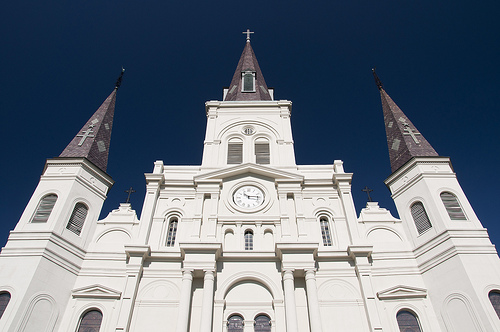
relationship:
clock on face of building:
[222, 175, 285, 215] [10, 19, 493, 328]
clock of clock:
[222, 175, 285, 215] [230, 179, 266, 213]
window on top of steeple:
[241, 70, 259, 95] [219, 32, 279, 106]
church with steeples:
[6, 21, 498, 330] [39, 26, 440, 193]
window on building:
[242, 221, 256, 250] [10, 19, 493, 328]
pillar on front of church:
[177, 272, 197, 331] [6, 21, 498, 330]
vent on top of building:
[235, 117, 256, 137] [10, 19, 493, 328]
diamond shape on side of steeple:
[382, 132, 407, 161] [366, 84, 442, 178]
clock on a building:
[222, 175, 285, 215] [10, 19, 493, 328]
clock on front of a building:
[222, 175, 285, 215] [10, 19, 493, 328]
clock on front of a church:
[222, 175, 285, 215] [6, 21, 498, 330]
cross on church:
[236, 24, 261, 45] [62, 63, 371, 321]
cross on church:
[236, 24, 261, 45] [77, 76, 437, 329]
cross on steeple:
[236, 24, 261, 45] [222, 36, 279, 90]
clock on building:
[237, 175, 319, 232] [132, 104, 360, 321]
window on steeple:
[234, 66, 259, 96] [214, 39, 293, 112]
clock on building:
[222, 175, 285, 215] [137, 98, 322, 308]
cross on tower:
[67, 120, 98, 147] [23, 96, 115, 322]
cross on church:
[235, 24, 270, 54] [125, 70, 396, 316]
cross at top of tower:
[236, 24, 261, 45] [210, 28, 291, 101]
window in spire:
[234, 66, 259, 96] [222, 23, 283, 105]